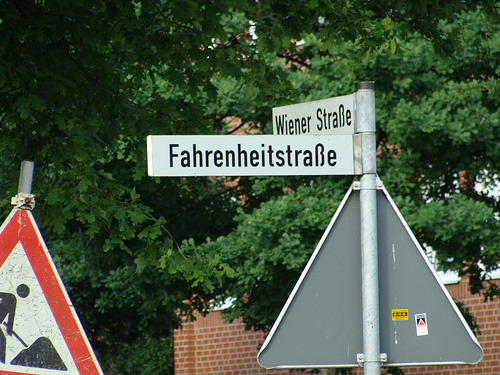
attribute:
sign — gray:
[257, 187, 479, 374]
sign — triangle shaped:
[252, 184, 490, 346]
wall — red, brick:
[171, 7, 498, 374]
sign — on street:
[146, 130, 356, 177]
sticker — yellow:
[388, 306, 412, 323]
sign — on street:
[3, 197, 72, 369]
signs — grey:
[116, 64, 402, 174]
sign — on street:
[108, 105, 408, 180]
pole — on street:
[339, 83, 391, 359]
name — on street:
[167, 138, 342, 171]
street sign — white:
[270, 87, 360, 134]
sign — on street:
[253, 175, 488, 369]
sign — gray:
[296, 194, 469, 356]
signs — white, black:
[145, 91, 363, 178]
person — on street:
[3, 245, 73, 370]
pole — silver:
[354, 79, 382, 372]